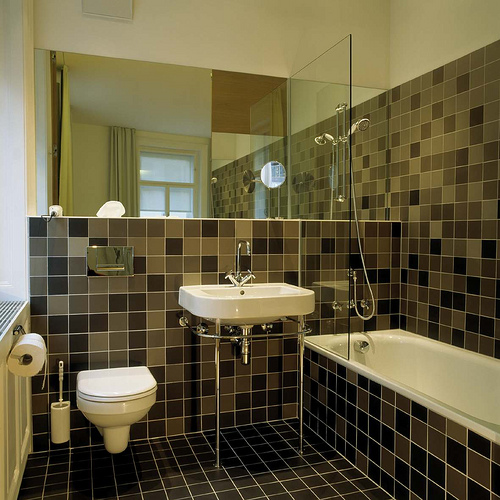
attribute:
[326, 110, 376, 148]
shower head — small, round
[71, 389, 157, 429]
toilet bowl — white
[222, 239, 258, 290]
sink fixture — silver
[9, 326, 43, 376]
roll — large, toilet paper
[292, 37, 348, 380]
panel — glass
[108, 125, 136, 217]
curtain — bathroom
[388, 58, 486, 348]
tiles — different shades of brown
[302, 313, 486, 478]
bathtub — full length, white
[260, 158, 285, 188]
mirror — small, round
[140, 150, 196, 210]
blinds — partly drawn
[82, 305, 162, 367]
tank — exterior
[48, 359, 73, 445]
brush — toilet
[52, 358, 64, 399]
handle — white